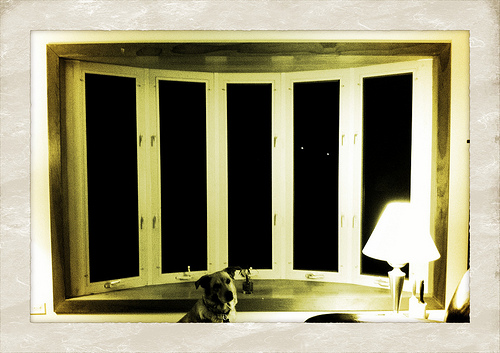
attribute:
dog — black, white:
[171, 266, 249, 320]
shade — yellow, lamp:
[362, 193, 460, 275]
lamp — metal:
[378, 265, 407, 319]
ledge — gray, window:
[64, 277, 427, 323]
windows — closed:
[78, 77, 438, 304]